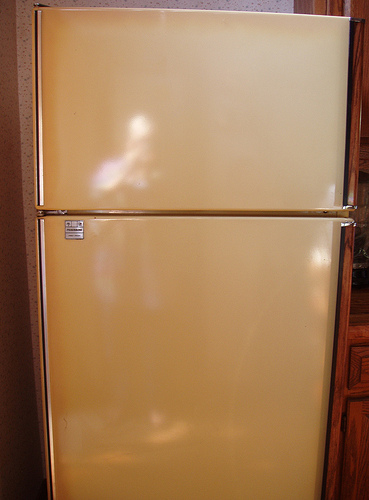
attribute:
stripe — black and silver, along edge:
[15, 31, 59, 491]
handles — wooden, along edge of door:
[324, 15, 356, 492]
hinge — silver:
[30, 206, 74, 219]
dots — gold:
[15, 33, 27, 68]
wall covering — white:
[11, 16, 42, 296]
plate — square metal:
[53, 212, 96, 250]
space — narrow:
[29, 196, 359, 236]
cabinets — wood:
[313, 21, 363, 487]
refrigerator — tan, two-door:
[34, 15, 344, 492]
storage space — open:
[343, 101, 364, 327]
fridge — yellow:
[14, 37, 338, 489]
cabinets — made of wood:
[337, 57, 365, 469]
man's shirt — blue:
[95, 157, 167, 238]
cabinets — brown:
[323, 28, 365, 495]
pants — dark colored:
[81, 290, 177, 407]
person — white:
[79, 97, 173, 225]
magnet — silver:
[59, 212, 98, 246]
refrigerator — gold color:
[6, 29, 360, 493]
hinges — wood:
[344, 193, 358, 216]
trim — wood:
[338, 10, 368, 212]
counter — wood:
[336, 314, 368, 357]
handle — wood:
[316, 223, 366, 498]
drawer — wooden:
[335, 345, 367, 375]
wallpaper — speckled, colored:
[3, 18, 39, 285]